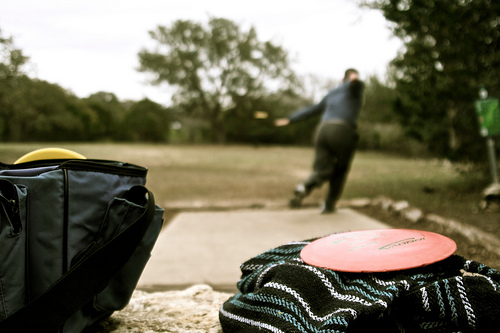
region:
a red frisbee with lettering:
[295, 221, 461, 279]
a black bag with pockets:
[1, 160, 162, 330]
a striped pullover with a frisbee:
[210, 224, 498, 331]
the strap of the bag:
[2, 182, 158, 321]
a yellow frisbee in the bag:
[12, 145, 83, 169]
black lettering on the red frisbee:
[381, 233, 434, 258]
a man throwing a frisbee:
[274, 48, 389, 215]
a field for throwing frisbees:
[6, 139, 498, 266]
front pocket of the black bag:
[97, 188, 164, 321]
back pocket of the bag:
[3, 183, 42, 324]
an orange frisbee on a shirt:
[299, 220, 451, 273]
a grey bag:
[5, 162, 150, 322]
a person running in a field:
[271, 65, 378, 200]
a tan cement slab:
[195, 212, 273, 252]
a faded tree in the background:
[138, 47, 268, 141]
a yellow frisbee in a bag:
[11, 137, 98, 195]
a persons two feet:
[260, 179, 346, 228]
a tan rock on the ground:
[156, 281, 220, 331]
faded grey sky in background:
[53, 22, 123, 69]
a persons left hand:
[256, 97, 292, 144]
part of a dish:
[375, 247, 434, 287]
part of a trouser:
[318, 128, 358, 169]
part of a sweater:
[329, 287, 382, 317]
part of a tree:
[207, 43, 271, 120]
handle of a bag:
[72, 265, 117, 295]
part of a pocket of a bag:
[138, 237, 159, 274]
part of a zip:
[3, 206, 30, 236]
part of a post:
[483, 129, 497, 184]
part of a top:
[314, 73, 355, 120]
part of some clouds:
[94, 62, 130, 94]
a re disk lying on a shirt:
[319, 228, 429, 265]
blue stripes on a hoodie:
[257, 290, 297, 318]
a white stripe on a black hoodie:
[279, 282, 298, 297]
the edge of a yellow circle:
[14, 139, 95, 159]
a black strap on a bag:
[54, 264, 129, 299]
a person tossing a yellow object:
[279, 59, 371, 208]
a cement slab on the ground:
[179, 203, 247, 258]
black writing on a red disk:
[379, 235, 434, 244]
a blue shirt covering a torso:
[326, 89, 353, 117]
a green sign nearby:
[471, 97, 498, 145]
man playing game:
[252, 67, 392, 216]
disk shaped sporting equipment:
[304, 213, 466, 281]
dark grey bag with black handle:
[4, 129, 168, 331]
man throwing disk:
[249, 58, 383, 225]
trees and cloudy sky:
[3, 22, 250, 159]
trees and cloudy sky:
[369, 5, 475, 155]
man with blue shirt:
[275, 62, 390, 217]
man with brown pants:
[275, 63, 400, 216]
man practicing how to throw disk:
[249, 46, 470, 292]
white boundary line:
[162, 191, 407, 220]